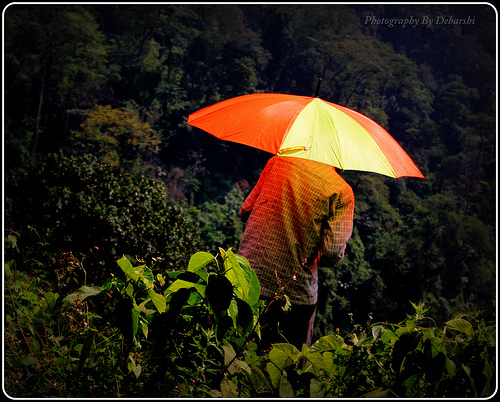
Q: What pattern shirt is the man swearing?
A: Small checkers.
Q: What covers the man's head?
A: Umbrella.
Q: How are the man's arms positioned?
A: Bent elbows in front.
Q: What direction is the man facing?
A: Away from camera.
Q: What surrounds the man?
A: Lush green bushes.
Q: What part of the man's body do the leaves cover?
A: Lower legs.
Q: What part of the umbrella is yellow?
A: Section section from the right.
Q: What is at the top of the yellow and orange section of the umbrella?
A: Black tip.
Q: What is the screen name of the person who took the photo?
A: Debarshi.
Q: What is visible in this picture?
A: An umbrella.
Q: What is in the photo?
A: A visible umbrella.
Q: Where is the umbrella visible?
A: In middle of photo.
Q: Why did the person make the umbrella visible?
A: Needed to use it.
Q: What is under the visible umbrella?
A: A person.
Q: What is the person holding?
A: An umbrella.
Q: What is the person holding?
A: An umbrella.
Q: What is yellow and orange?
A: An umbrella.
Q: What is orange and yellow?
A: An umbrella.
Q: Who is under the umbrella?
A: A man.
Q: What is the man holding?
A: An Umbrella.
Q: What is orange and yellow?
A: An umbrella.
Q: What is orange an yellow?
A: An umbrella.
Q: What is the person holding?
A: Umbrella.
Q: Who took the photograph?
A: Debarshi.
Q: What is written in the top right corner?
A: Photography by Debarsbi.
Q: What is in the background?
A: Trees.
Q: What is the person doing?
A: Walking.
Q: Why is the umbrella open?
A: To protect from the sun.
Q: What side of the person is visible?
A: Back.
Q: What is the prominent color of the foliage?
A: Green.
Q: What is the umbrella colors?
A: Red and yellow.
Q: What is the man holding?
A: Umbrella.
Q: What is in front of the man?
A: Shrubs.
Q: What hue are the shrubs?
A: Green.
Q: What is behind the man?
A: Trees.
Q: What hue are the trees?
A: Green.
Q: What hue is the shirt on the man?
A: White and gray.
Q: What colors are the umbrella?
A: Red and yellow.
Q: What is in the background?
A: Trees.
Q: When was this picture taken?
A: During the day.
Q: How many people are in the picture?
A: 1.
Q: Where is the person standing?
A: Outdoors.